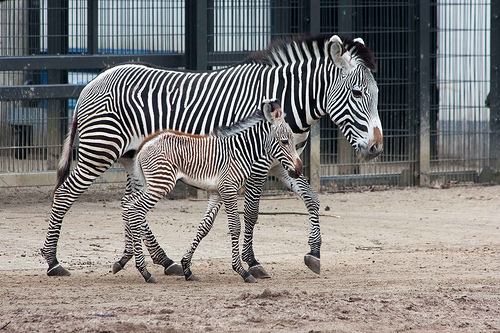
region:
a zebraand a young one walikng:
[37, 32, 357, 332]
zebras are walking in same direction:
[103, 48, 393, 310]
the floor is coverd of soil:
[263, 289, 330, 323]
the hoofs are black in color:
[103, 257, 162, 294]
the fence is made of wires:
[396, 59, 498, 181]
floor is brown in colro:
[282, 266, 423, 331]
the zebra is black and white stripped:
[92, 104, 227, 171]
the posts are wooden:
[405, 99, 461, 184]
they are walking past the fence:
[91, 39, 366, 261]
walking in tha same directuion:
[151, 92, 409, 262]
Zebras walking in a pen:
[37, 37, 383, 280]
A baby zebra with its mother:
[112, 107, 300, 288]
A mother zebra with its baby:
[40, 36, 382, 284]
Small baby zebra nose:
[293, 157, 304, 171]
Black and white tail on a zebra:
[50, 105, 80, 188]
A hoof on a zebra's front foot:
[305, 255, 323, 272]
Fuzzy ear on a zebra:
[329, 38, 346, 67]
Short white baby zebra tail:
[131, 156, 148, 186]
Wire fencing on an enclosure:
[437, 2, 490, 171]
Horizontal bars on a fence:
[2, 56, 87, 101]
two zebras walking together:
[36, 42, 381, 280]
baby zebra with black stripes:
[125, 107, 307, 281]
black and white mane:
[241, 33, 379, 75]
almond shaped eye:
[351, 85, 363, 95]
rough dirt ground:
[65, 275, 408, 330]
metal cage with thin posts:
[14, 5, 494, 181]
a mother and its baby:
[34, 31, 382, 276]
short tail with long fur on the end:
[45, 99, 84, 185]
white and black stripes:
[114, 80, 216, 120]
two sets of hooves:
[36, 242, 330, 284]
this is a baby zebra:
[103, 96, 306, 296]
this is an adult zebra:
[43, 25, 416, 303]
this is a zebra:
[93, 90, 333, 278]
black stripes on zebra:
[94, 73, 236, 121]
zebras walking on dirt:
[29, 2, 464, 330]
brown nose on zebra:
[283, 150, 308, 192]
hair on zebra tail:
[35, 105, 99, 203]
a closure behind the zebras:
[19, 2, 491, 207]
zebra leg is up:
[272, 194, 364, 295]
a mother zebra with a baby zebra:
[38, 45, 395, 283]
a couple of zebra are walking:
[33, 30, 387, 287]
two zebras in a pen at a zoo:
[40, 31, 390, 283]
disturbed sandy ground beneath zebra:
[243, 276, 371, 328]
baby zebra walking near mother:
[112, 100, 306, 283]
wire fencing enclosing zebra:
[423, 13, 480, 186]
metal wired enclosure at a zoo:
[3, 4, 60, 206]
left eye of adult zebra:
[352, 88, 361, 98]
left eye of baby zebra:
[277, 136, 287, 146]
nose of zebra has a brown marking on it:
[361, 120, 385, 154]